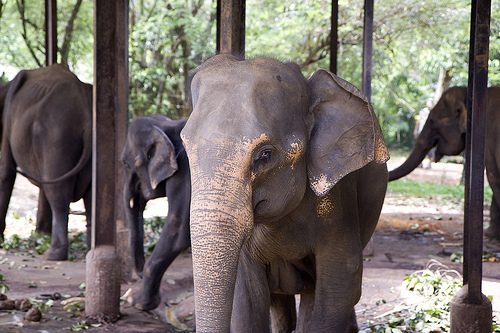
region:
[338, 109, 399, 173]
ear of an elephant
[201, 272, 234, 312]
part of a trunk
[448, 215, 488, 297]
part of a post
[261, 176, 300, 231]
part of a jaw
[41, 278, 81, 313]
part of the ground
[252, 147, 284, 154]
part of an eye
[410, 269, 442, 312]
part of a plant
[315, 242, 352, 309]
part of a leg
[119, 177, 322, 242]
part of an elephant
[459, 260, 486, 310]
part of a metal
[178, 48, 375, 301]
this is an elephant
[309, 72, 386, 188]
this is the elephant's ear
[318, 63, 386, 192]
the ear is big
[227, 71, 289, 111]
the fur is grey in color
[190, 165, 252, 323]
this is the elephant's trunk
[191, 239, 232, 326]
the trunk is long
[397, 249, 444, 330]
this is the grass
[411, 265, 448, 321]
the grass is green in color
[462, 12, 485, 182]
this is a pillar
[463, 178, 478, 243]
the pillar is metallic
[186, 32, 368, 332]
this is a elephant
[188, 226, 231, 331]
this is the trunk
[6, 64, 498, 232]
they are four elephants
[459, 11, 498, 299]
this is a pole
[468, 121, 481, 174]
the pole is metallic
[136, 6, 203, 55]
this is a tree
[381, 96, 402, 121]
the tree has green leaves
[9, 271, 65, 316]
this is the ground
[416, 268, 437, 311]
there are some leaves on the ground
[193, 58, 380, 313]
the elephant is huge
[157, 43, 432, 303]
an elephant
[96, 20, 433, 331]
an elephant standing up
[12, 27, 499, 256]
elephants standing all around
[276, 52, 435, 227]
an elephants ear flapping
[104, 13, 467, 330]
an elephant during the day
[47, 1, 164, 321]
a tall wooden pole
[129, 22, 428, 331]
an elephant standing during the day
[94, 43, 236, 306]
an elephant walking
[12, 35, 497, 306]
four elephants standing around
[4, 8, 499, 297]
four different size elephants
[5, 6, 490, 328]
elephants in a shaded area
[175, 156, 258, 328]
trunk of an elephant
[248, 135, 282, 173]
left eye of an elephant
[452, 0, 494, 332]
metal beam near the elephants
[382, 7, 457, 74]
green trees in the background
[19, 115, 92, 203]
tail of an elephant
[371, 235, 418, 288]
dirt ground by the elephants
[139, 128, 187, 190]
left ear of an elephant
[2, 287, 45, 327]
feces of an elephant on the ground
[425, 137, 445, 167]
opened mouth of an elephant